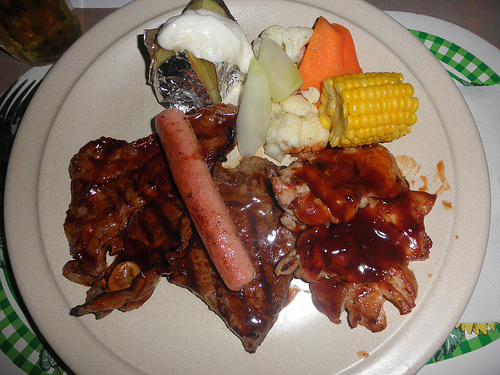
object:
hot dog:
[151, 110, 258, 290]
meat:
[271, 144, 408, 228]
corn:
[316, 70, 420, 147]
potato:
[264, 115, 321, 156]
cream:
[156, 8, 251, 71]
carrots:
[297, 16, 342, 91]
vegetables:
[258, 34, 305, 102]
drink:
[0, 0, 82, 67]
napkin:
[461, 86, 499, 322]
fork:
[1, 62, 58, 118]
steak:
[61, 104, 290, 354]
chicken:
[271, 144, 436, 331]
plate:
[0, 0, 491, 375]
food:
[153, 109, 254, 292]